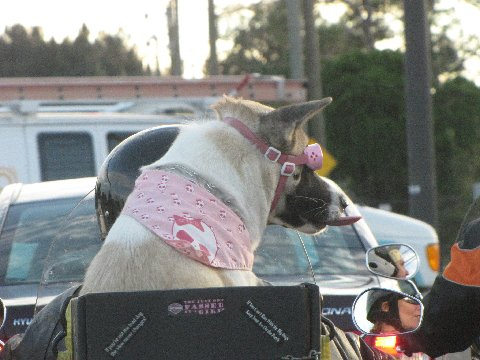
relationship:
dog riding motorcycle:
[75, 94, 360, 360] [1, 288, 425, 360]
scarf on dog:
[121, 170, 254, 271] [75, 94, 360, 360]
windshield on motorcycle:
[35, 187, 319, 316] [1, 288, 425, 360]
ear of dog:
[265, 97, 332, 152] [75, 94, 360, 360]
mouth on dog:
[288, 167, 361, 236] [75, 94, 360, 360]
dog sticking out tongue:
[75, 94, 360, 360] [331, 216, 361, 225]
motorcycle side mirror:
[1, 288, 425, 360] [351, 288, 423, 335]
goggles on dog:
[211, 118, 323, 223] [75, 94, 360, 360]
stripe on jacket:
[444, 244, 480, 286] [412, 219, 480, 352]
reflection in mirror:
[352, 288, 421, 334] [351, 288, 423, 335]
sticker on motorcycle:
[168, 298, 228, 316] [1, 288, 425, 360]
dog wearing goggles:
[75, 94, 360, 360] [211, 118, 323, 223]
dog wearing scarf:
[75, 94, 360, 360] [121, 170, 254, 271]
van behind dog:
[0, 76, 307, 195] [75, 94, 360, 360]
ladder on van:
[2, 76, 309, 103] [0, 76, 307, 195]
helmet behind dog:
[95, 125, 184, 242] [75, 94, 360, 360]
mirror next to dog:
[351, 288, 423, 335] [75, 94, 360, 360]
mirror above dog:
[351, 288, 423, 335] [75, 94, 360, 360]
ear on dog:
[265, 97, 332, 152] [75, 94, 360, 360]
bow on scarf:
[176, 216, 204, 231] [121, 170, 254, 271]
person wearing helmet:
[4, 126, 399, 360] [95, 125, 184, 242]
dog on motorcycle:
[75, 94, 360, 360] [1, 288, 425, 360]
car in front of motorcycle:
[0, 175, 402, 360] [1, 288, 425, 360]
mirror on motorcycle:
[351, 288, 423, 335] [1, 288, 425, 360]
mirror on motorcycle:
[367, 245, 419, 281] [367, 242, 480, 360]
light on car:
[377, 336, 396, 348] [0, 175, 402, 360]